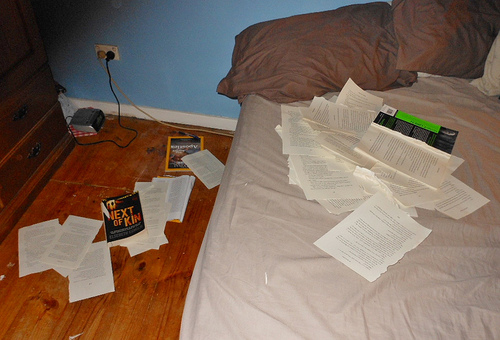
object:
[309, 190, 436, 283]
paper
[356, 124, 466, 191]
paper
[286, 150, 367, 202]
paper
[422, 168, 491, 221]
paper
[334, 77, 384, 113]
paper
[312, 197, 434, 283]
paper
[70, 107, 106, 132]
alarm clock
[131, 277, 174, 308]
floor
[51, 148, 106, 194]
floor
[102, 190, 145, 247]
book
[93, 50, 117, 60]
plug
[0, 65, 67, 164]
drawer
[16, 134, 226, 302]
pages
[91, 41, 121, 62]
socket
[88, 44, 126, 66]
socket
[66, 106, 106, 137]
radio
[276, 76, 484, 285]
book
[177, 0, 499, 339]
bed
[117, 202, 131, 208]
black color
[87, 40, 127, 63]
power socket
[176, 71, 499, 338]
sheet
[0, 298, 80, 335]
floor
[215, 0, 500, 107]
cover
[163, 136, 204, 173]
book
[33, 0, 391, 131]
wall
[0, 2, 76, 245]
chest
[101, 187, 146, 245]
cover